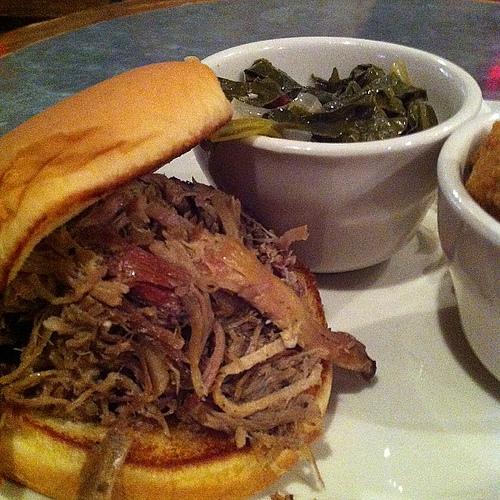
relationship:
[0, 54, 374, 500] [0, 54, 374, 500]
bread roll has bread roll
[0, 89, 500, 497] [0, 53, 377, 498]
plate has food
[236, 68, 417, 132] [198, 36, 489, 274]
spinach in bowl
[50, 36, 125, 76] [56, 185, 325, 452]
blue table has food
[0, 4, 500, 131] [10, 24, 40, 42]
blue table has edge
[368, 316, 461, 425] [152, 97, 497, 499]
shadow cast on plate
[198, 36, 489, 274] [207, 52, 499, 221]
bowl has food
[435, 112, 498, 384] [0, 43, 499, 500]
bowl has food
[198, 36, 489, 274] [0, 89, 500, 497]
bowl on plate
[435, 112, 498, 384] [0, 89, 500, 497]
bowl on plate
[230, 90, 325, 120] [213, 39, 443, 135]
onion in spinach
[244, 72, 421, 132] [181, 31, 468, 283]
kale in bowl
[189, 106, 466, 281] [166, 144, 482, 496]
bowl on plate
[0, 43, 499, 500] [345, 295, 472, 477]
food on plate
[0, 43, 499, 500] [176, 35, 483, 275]
food on cup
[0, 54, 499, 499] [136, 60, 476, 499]
food on plate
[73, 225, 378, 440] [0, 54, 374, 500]
meat on bread roll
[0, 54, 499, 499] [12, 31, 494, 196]
food on table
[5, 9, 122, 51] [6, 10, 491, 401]
edge of table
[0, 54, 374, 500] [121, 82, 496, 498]
bread roll on plate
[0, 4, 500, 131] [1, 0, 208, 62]
blue table has wooden edge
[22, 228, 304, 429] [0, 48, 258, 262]
meat on bun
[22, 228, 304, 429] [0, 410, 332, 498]
meat on bun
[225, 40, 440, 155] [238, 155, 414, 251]
greens in cup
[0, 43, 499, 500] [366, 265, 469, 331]
food on plate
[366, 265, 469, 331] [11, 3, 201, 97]
plate on table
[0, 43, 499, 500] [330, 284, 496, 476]
food on plate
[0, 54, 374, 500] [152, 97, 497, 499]
bread roll on plate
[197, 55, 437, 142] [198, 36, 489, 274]
spinach in bowl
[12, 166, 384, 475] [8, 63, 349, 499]
pulled pork in sandwich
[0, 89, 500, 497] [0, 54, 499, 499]
plate of food